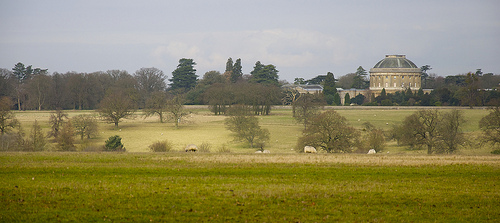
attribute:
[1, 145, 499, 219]
grass — green, large, short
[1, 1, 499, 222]
photo — outdoor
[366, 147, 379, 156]
animals — grazing, white, eating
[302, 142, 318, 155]
animals — grazing, white, eating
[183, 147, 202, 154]
animals — grazing, eating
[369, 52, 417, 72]
roof — dome, gray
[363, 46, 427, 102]
building — large, brick, brown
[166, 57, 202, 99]
tree — large, evergreen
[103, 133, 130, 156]
tree — smal, evergreen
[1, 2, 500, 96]
day — clear, sunny, cloudy, grey, blue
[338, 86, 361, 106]
entrance — archway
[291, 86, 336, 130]
trees — dry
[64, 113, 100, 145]
trees — dry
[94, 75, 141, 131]
trees — dry